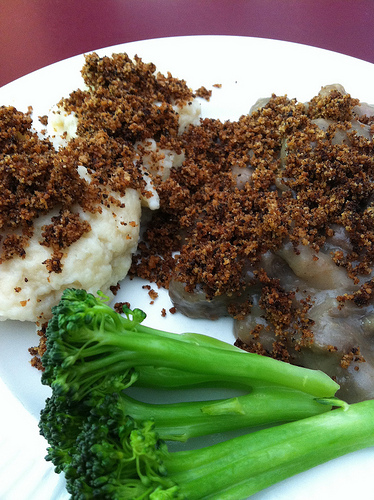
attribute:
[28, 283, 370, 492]
vegetable — green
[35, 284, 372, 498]
broccoli — up front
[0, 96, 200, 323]
mashed potatoes — white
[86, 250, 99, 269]
potatoes — MASHED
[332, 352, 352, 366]
bits — BACON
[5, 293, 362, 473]
broccoli — SPEARS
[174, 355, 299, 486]
spears — BROCCOLI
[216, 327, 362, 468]
spears — BROCCOLI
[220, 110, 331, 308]
food — GRAVY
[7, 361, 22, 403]
plate — ROUND, SHAPE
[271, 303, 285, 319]
bits — BACON, BROWN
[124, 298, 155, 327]
broccolli — PIECE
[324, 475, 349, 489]
plate — THREE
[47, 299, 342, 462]
brocolli — PIECE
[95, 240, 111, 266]
potatoes — MASHED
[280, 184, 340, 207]
seasoning — TOP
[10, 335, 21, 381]
plate — WHITE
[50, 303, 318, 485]
items — VEGETABLE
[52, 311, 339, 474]
broccoli — TOP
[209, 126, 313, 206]
seasoning — HEAVY, BROWN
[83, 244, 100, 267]
potatoes — MASHED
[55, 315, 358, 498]
broccoli — STEAMED, PIECE